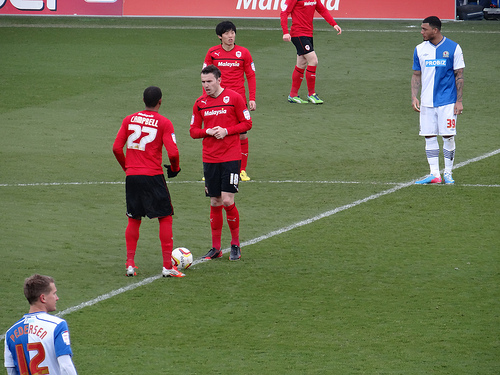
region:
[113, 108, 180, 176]
a red soccer jersey with the number 27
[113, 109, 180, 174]
a red soccer jersey with the players name Campbell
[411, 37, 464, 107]
a blue and white soccer jersey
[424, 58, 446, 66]
the logo name Probiz is written on the jersey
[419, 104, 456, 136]
white soccer shorts with the number 39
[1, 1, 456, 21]
advertising on the wall behind the field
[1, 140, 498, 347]
white chalk lines painted on the field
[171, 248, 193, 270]
a white, red and yellow soccer ball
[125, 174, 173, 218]
black soccer shorts on the soccer player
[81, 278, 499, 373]
green grass on the soccer field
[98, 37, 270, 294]
Soccer players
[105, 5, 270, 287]
Soccer players wearing red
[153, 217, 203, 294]
A soccer ball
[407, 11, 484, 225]
A soccer player wearing blue and white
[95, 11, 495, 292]
Professional soccer players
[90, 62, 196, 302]
A soccer player wearing black shorts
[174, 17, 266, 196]
A asian soccer player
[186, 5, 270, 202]
A soccer player wearing yellow shoes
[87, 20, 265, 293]
Soccer players ready to kick off the ball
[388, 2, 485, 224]
A soccer player wearing white shorts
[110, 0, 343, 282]
The players in the red uniform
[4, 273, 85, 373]
The player with number 12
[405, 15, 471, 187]
The player with the number 39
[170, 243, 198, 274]
The soccer ball on the line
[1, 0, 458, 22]
the red signs in the background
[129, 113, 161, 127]
The name on the back of a red player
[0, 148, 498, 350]
The line running down the middle of the field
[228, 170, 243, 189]
The number on the black shorts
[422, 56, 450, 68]
The writing on the front of a blue jersey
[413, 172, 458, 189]
The blue and red cleats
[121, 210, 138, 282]
the leg of a player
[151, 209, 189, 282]
the leg of a player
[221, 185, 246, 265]
the leg of a player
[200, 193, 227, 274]
the leg of a player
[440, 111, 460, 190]
the leg of a player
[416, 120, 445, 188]
the leg of a player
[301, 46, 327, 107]
the leg of a player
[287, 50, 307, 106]
the leg of a player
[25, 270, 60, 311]
the head of a player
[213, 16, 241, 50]
the head of a player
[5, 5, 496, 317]
Men playing soccer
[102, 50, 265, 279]
Two soccer players talking.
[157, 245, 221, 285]
Soccer ball on field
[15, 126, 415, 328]
Lines on a soccer field.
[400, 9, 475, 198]
Soccer player in blue and white uniform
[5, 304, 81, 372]
Back of a soccer player with writing on uniform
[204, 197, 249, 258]
Red soccer socks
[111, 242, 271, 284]
Soccer cleats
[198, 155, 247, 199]
Black soccer shorts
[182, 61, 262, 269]
Man standing on soccer field